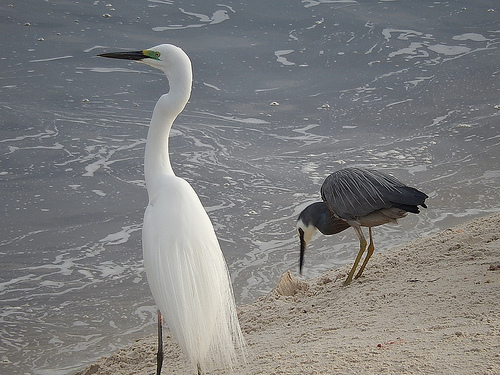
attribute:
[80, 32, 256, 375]
heron — white, large, tall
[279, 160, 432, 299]
bird — white, black, pecking, digging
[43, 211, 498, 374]
sand — tan, dry, overfeet, brown, wet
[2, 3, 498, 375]
water — gray, swirls, white, calm, murky, grey, foam, pond, reflecting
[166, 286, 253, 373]
feathers — long, wispy, hairlike, white, flowing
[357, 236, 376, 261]
knees — backwards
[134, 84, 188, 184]
neck — white, long, powerful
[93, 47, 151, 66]
beak — black, long, pointy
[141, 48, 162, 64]
spot — yellow, green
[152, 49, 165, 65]
eye — heron, yellow, green